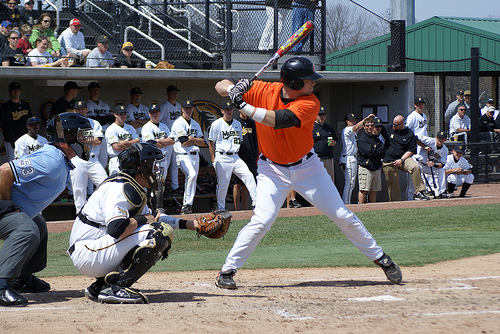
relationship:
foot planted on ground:
[373, 249, 409, 293] [293, 280, 493, 319]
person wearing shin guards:
[64, 141, 231, 301] [112, 247, 162, 289]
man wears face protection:
[0, 110, 94, 314] [65, 112, 99, 167]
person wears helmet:
[65, 143, 235, 306] [117, 143, 170, 192]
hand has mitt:
[184, 214, 221, 236] [196, 210, 239, 244]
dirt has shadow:
[281, 294, 401, 334] [288, 281, 385, 288]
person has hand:
[65, 143, 235, 306] [184, 214, 221, 236]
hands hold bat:
[224, 75, 258, 109] [218, 19, 320, 93]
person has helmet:
[65, 143, 235, 306] [114, 141, 179, 193]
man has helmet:
[208, 47, 411, 299] [280, 53, 321, 93]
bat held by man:
[218, 19, 320, 93] [208, 47, 411, 299]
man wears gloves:
[208, 47, 411, 299] [224, 75, 258, 109]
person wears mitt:
[65, 143, 235, 306] [196, 210, 239, 244]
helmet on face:
[117, 143, 170, 192] [139, 162, 161, 194]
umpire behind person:
[0, 110, 94, 314] [65, 143, 235, 306]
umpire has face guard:
[0, 110, 94, 314] [65, 112, 99, 167]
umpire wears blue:
[0, 110, 94, 314] [11, 140, 74, 215]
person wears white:
[65, 143, 235, 306] [80, 180, 125, 274]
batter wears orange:
[208, 47, 411, 299] [240, 67, 327, 167]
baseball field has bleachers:
[15, 62, 497, 305] [7, 6, 225, 81]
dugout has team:
[29, 76, 418, 203] [7, 85, 258, 208]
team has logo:
[7, 85, 258, 208] [221, 126, 245, 145]